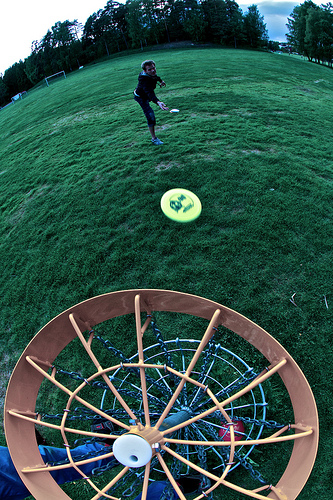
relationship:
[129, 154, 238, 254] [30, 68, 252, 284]
frisbee over grass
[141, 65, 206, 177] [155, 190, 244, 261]
man throwing frisbee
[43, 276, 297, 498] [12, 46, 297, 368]
goal on field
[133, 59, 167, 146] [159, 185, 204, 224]
man threw frisbee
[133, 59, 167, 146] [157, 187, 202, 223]
man throwing a frisbee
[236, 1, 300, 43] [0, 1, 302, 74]
cloud in sky